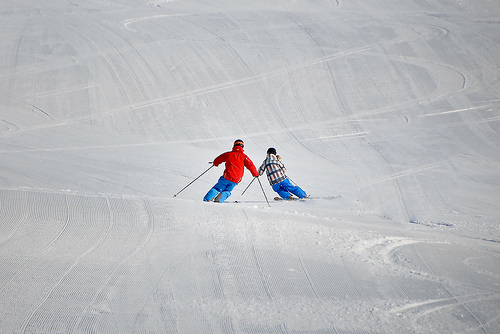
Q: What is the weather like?
A: Cold.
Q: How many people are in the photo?
A: Two.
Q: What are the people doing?
A: Skiing.